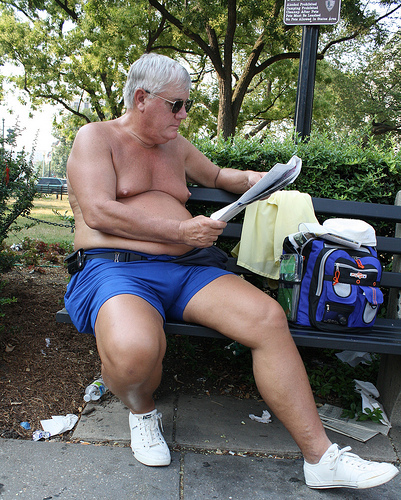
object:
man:
[61, 49, 400, 491]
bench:
[89, 182, 399, 356]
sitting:
[64, 219, 230, 331]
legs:
[177, 255, 338, 471]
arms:
[70, 179, 227, 249]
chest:
[113, 145, 193, 200]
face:
[144, 95, 188, 136]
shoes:
[126, 409, 171, 466]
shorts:
[64, 246, 234, 331]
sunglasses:
[164, 93, 194, 118]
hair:
[126, 52, 190, 99]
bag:
[280, 228, 383, 327]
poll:
[290, 0, 319, 130]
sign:
[282, 0, 342, 27]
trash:
[321, 380, 389, 441]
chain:
[43, 220, 73, 232]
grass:
[26, 197, 68, 226]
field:
[36, 185, 64, 218]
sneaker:
[301, 437, 395, 488]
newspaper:
[213, 152, 302, 223]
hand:
[182, 214, 227, 250]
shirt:
[267, 188, 315, 264]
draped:
[236, 188, 321, 281]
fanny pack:
[124, 247, 223, 265]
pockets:
[316, 282, 384, 327]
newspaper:
[318, 400, 389, 440]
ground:
[319, 397, 401, 461]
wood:
[318, 195, 400, 219]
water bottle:
[81, 380, 106, 403]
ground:
[0, 396, 109, 488]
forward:
[157, 58, 190, 85]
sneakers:
[126, 409, 169, 465]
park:
[232, 1, 395, 99]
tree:
[151, 0, 298, 127]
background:
[195, 1, 401, 133]